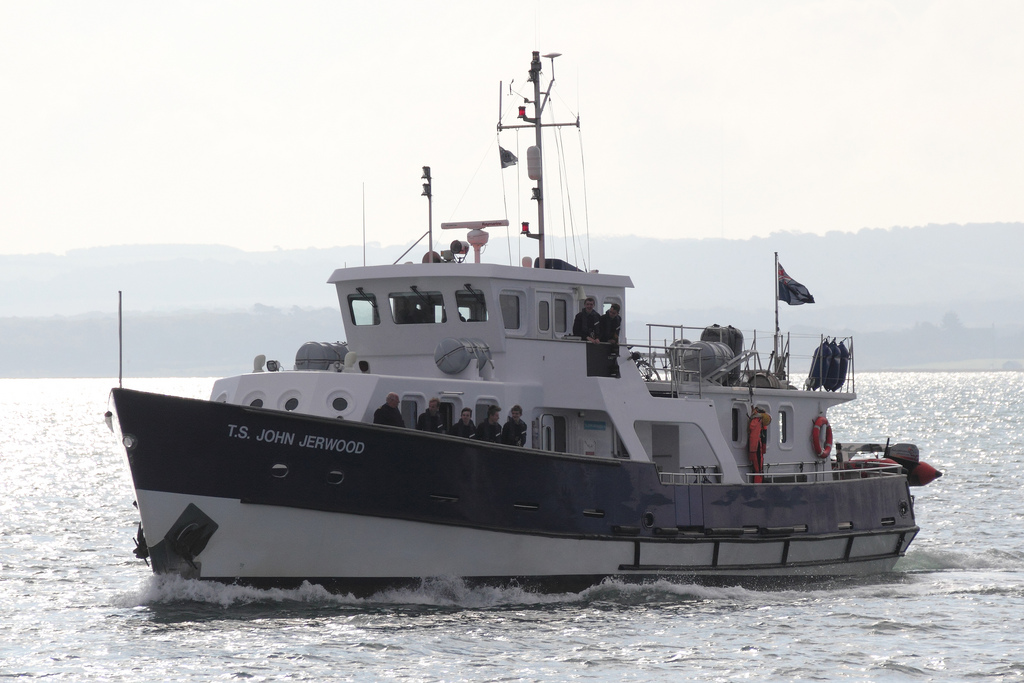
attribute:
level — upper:
[255, 250, 874, 393]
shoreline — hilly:
[8, 220, 1015, 378]